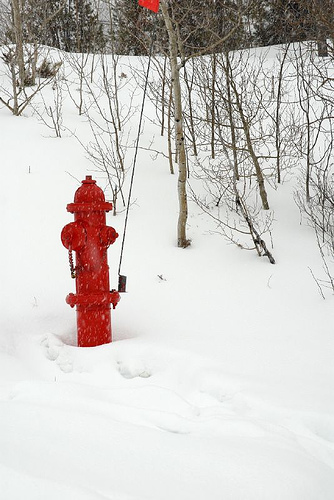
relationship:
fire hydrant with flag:
[59, 173, 122, 348] [114, 0, 161, 296]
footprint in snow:
[37, 334, 60, 360] [0, 36, 333, 496]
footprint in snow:
[55, 351, 74, 373] [0, 36, 333, 496]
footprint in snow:
[113, 352, 136, 379] [0, 36, 333, 496]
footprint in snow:
[135, 355, 152, 377] [0, 36, 333, 496]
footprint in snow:
[152, 414, 193, 435] [0, 36, 333, 496]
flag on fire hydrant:
[136, 1, 158, 12] [59, 173, 122, 348]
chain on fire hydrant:
[66, 244, 79, 281] [59, 173, 122, 348]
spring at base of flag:
[116, 272, 128, 293] [140, 1, 169, 19]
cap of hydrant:
[62, 169, 120, 215] [36, 160, 172, 392]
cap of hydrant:
[105, 228, 119, 242] [60, 171, 126, 351]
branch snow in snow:
[217, 195, 280, 260] [9, 100, 317, 498]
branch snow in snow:
[81, 125, 131, 174] [9, 100, 317, 498]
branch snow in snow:
[31, 88, 63, 141] [9, 100, 317, 498]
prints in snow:
[116, 355, 156, 383] [0, 36, 333, 496]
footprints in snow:
[40, 338, 76, 374] [0, 36, 333, 496]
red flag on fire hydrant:
[111, 0, 166, 287] [59, 173, 122, 348]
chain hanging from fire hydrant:
[66, 244, 79, 281] [59, 173, 122, 348]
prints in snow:
[85, 346, 230, 439] [0, 36, 333, 496]